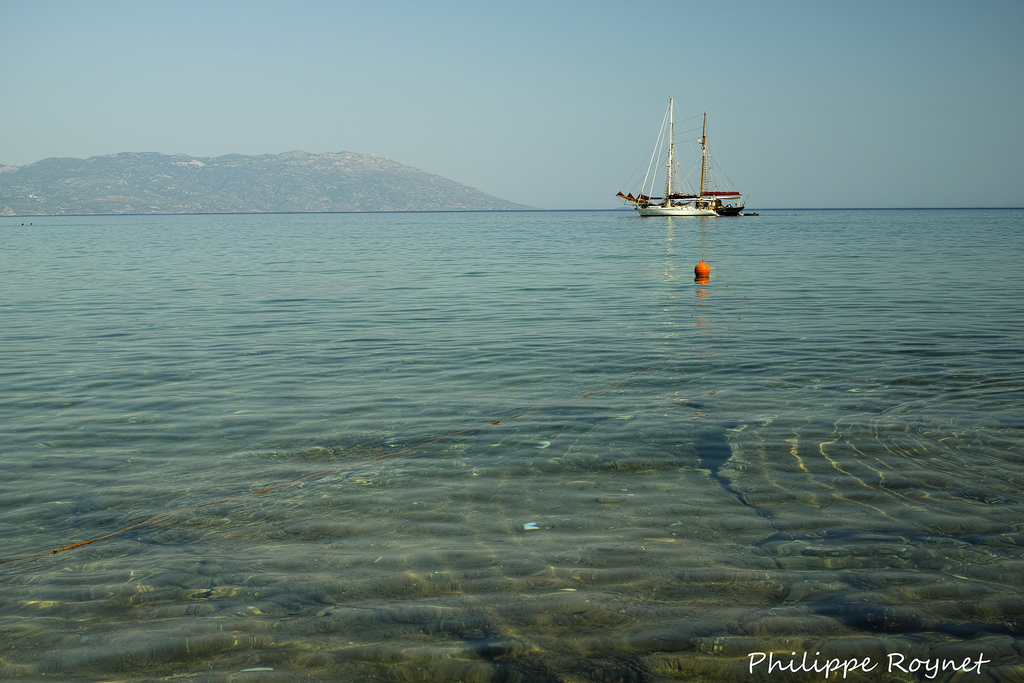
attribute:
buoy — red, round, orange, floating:
[679, 254, 709, 299]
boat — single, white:
[597, 114, 733, 229]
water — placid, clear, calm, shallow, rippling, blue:
[23, 348, 1004, 674]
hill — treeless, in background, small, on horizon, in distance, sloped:
[9, 151, 527, 189]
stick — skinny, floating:
[16, 490, 239, 608]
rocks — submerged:
[220, 422, 988, 669]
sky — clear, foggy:
[673, 15, 1011, 151]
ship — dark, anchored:
[574, 81, 761, 235]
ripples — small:
[413, 379, 990, 614]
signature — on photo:
[747, 614, 990, 682]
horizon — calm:
[750, 198, 987, 224]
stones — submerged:
[23, 476, 336, 682]